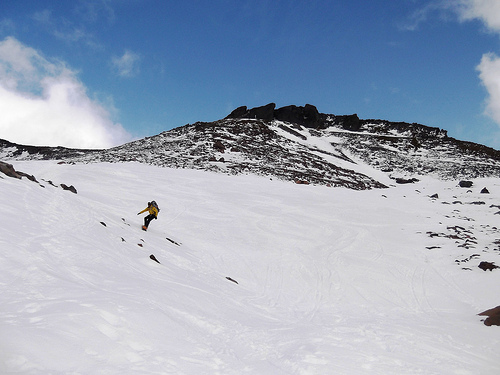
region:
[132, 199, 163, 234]
person riding a snowboard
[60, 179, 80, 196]
black rock in the snow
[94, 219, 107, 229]
black rock in the snow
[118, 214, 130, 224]
black rock in the snow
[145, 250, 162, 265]
black rock in the snow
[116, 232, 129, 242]
black rock in the snow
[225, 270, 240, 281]
black rock in the snow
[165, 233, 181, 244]
black rock in the snow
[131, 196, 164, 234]
person wearing yellow jacket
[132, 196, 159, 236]
person wearing a backpack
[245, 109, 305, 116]
Rocks on the summit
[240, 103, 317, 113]
Jugged rocks rising up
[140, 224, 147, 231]
A red snow shoe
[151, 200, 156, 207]
A greenish back pack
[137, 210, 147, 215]
A man's outstreched arm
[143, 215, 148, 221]
The bent knee of a man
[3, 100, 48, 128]
White clouds in the sky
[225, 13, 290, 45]
A clear blue sky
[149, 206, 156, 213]
A hiker's yellow shirt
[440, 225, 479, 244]
Rocks sticking out in snow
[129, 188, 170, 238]
a skier on a hill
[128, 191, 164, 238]
a skier wears a yellow top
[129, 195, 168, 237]
skier is bend forward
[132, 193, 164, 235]
skier carry a backpack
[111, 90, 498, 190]
a mountain cover with some snow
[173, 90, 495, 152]
plants on top of the mountain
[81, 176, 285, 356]
skier on a hill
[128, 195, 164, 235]
right hand of skier is extended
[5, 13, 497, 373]
a blue sky over a mountain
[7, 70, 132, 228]
white in the sky and mountain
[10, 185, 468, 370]
Expanse of snow covered ground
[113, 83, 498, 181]
Dome shaped top of a hill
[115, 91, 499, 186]
Rocky hilltop without much snow cover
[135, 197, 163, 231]
Person scaling the snow filled hillside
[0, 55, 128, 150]
White clouds in the sky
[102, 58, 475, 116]
Clear blue part of the sky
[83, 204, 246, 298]
Rock pieces in the snow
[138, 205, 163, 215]
Thick yellow colored jacket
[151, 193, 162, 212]
Very large dark backpack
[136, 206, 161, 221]
Person swinging arms out in stride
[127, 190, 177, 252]
a person snowboarding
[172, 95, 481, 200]
a rocky mountain top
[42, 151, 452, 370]
a snowy ski slope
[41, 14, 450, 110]
a patch of mostly clear blue sky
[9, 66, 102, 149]
a large white cloud on the horizon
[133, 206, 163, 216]
a skier's yellow coat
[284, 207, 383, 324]
tracks in the snow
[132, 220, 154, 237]
a person's snowboard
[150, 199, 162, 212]
a pack on a boarder's back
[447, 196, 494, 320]
scattered rocks next to a ski slope